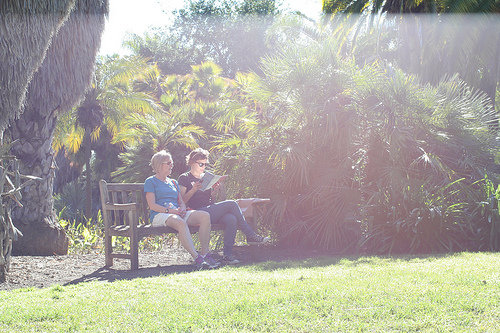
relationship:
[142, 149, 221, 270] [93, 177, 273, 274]
woman sitting on bench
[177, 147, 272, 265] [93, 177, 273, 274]
woman sitting on bench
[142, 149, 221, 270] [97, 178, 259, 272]
woman on bench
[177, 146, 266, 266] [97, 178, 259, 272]
woman on bench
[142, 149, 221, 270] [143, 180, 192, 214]
woman wearing shirt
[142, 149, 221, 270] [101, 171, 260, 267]
woman sitting on bench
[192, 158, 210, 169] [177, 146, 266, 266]
black sunglasses on woman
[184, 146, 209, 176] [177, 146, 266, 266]
hair on woman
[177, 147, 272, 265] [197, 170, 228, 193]
woman holding book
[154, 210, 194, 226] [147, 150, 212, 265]
shorts on woman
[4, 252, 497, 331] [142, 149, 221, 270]
grass front of woman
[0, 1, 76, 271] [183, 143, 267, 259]
tree behind woman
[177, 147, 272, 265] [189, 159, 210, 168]
woman in black sunglasses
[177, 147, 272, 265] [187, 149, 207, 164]
woman with hair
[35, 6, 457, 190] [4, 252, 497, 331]
sunshine shines on grass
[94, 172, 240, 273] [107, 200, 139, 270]
bench with arm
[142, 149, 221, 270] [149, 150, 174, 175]
woman with hair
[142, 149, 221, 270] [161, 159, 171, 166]
woman with glasses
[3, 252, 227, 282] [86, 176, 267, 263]
path leads to bench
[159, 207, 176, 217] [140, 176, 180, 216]
wrist on arm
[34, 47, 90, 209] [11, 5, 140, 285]
bark on tree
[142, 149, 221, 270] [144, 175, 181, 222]
woman wearing blue shirt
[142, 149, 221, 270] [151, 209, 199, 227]
woman wearing shorts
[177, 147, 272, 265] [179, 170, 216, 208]
woman wearing shirt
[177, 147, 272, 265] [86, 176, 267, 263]
woman on bench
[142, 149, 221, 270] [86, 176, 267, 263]
woman on bench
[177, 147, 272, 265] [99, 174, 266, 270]
woman on bench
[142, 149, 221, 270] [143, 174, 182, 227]
woman in blue shirt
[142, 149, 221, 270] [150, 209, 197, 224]
woman in shorts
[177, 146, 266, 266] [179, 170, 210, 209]
woman in shirt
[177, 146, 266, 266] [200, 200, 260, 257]
woman in jeans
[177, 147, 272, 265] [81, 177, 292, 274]
woman on bench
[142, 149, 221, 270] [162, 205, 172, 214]
woman wearing watch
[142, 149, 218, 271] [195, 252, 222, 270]
woman wearing sneakers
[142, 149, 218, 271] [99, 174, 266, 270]
woman sitting on bench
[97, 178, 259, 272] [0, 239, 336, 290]
bench on path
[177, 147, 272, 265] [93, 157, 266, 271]
woman sitting on bench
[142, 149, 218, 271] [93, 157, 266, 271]
woman sitting on bench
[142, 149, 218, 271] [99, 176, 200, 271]
woman sitting on bench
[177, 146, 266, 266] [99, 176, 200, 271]
woman sitting on bench